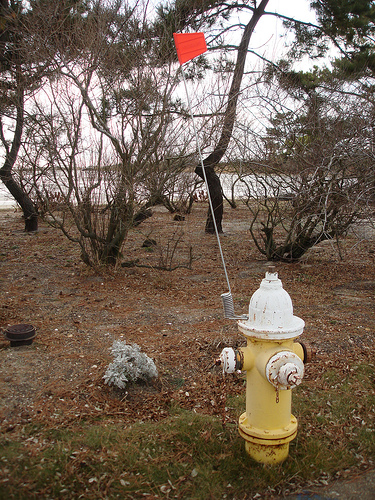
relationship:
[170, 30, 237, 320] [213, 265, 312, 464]
flag attached to hydrant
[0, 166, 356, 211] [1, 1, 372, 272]
lake behind trees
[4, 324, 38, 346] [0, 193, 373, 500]
pipe in ground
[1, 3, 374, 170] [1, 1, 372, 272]
sky peeping through trees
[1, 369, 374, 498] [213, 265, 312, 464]
grass surrounding hydrant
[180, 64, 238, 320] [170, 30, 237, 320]
pole holding flag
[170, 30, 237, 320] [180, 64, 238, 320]
flag on pole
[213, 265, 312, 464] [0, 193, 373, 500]
hydrant on ground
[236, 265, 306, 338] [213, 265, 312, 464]
top of hydrant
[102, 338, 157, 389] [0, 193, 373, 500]
bush on ground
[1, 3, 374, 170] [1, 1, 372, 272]
sky behind trees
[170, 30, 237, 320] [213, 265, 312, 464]
flag on hydrant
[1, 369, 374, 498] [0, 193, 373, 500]
grass on ground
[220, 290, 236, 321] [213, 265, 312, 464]
coil attached to hydrant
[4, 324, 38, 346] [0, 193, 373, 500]
pipe protruding from ground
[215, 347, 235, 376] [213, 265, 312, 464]
cap on hydrant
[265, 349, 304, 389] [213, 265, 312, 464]
cap on hydrant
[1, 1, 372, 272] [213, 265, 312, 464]
trees behind hydrant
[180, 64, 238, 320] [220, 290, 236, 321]
pole has coil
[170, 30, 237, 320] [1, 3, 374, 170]
flag in sky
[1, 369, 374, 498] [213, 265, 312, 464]
grass near hydrant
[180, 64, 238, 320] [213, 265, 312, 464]
pole attached to hydrant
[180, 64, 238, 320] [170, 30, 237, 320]
pole with flag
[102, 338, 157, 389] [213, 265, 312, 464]
bush next to hydrant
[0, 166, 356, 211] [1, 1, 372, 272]
lake beyond trees